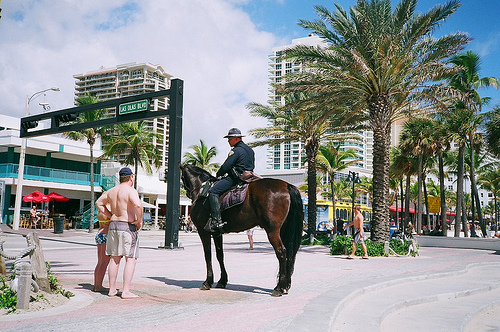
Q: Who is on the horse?
A: An officer.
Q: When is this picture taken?
A: During daytime.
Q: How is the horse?
A: Brown and strong.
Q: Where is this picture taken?
A: A public place.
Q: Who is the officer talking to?
A: To a couple in swimwear.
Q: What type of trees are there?
A: Palm trees.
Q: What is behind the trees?
A: Buildings.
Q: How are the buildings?
A: Tall multi storey buildings.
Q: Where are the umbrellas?
A: Near the building.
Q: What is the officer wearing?
A: A blue uniform and hat.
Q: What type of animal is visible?
A: Horse.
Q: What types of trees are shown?
A: Palm.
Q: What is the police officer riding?
A: Horse.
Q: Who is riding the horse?
A: Police officer.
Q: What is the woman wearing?
A: Bikini.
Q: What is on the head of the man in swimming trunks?
A: Hat.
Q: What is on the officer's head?
A: Hat.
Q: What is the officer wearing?
A: Uniform.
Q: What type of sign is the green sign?
A: Street sign.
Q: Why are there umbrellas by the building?
A: Shade.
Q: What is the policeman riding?
A: A horse.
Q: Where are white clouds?
A: In the sky.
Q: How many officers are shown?
A: One.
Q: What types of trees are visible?
A: Palm.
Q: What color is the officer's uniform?
A: Black.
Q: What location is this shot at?
A: Beach.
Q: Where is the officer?
A: Horseback.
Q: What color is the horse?
A: Brown.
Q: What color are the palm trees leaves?
A: Green.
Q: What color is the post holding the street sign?
A: Black.